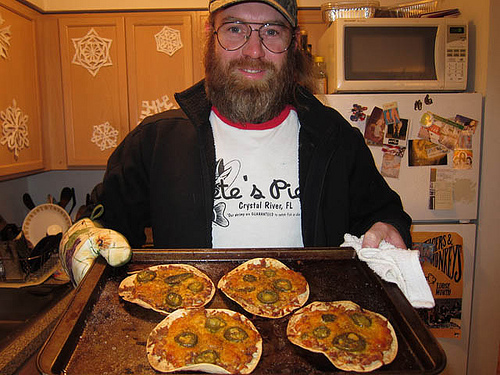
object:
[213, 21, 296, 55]
glasses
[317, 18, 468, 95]
microwave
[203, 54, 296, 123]
beard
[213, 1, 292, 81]
face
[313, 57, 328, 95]
bottle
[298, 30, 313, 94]
bottle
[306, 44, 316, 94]
bottle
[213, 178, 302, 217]
words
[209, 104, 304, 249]
shirt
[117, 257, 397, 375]
cookie sheet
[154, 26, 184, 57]
decoration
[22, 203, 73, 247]
dish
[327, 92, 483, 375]
fridge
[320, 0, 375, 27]
container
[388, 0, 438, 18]
container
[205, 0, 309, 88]
head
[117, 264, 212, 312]
pizza toritlla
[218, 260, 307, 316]
pizza toritlla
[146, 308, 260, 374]
pizza toritlla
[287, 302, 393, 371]
pizza toritlla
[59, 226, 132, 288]
hand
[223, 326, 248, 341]
jalapeno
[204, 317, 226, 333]
jalapeno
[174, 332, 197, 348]
jalapeno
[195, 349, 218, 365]
jalapeno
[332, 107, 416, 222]
arm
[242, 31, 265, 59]
nose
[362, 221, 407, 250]
hand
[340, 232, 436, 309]
kitchen towel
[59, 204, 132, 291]
glove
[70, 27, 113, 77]
decorations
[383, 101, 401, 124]
magnet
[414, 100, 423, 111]
magnet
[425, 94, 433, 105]
magnet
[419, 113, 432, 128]
magnet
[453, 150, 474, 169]
magnet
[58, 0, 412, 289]
man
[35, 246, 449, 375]
pan